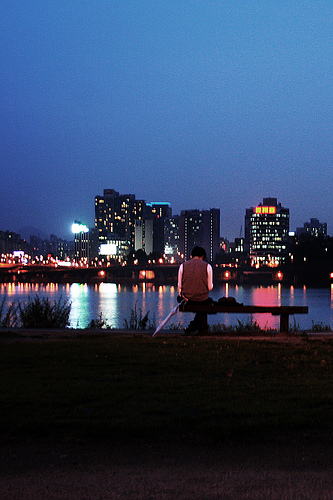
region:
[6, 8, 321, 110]
Large blue night sky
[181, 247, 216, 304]
A small boy sitting by the river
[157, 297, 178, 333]
Silver toy sword sitting by a small boy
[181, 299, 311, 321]
A black bench by the river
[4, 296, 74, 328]
Small green shrubs growing by the river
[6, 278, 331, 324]
River in front of the city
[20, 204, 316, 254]
Cityscape with large lit buildings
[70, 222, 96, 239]
Glowing blue size on building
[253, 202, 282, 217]
Glowing red sign on city building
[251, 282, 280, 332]
Red light reflection on river's surface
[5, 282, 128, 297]
The reflection of bright pretty lights on the water.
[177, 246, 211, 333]
A man deep in thought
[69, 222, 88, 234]
Bright lights that make it so people can see.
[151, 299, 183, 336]
A light colored umbrella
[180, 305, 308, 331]
A park bench for people to sit on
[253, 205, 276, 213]
Windows all light up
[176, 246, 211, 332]
Gentleman in a sweater vest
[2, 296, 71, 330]
Green foliage in the moonlight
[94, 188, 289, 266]
Pretty buildings and lights at dusk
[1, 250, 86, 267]
The signs of a night life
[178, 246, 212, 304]
the back of a man sitting on a bench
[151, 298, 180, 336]
a white umbrella leaning against a bench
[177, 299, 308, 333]
a concrete bench by the river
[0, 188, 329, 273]
the city skyline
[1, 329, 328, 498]
mown grass in a riverside park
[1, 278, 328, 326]
reflective calm water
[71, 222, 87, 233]
bright white lights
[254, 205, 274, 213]
a series of three glowing orange lights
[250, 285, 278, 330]
pink light reflecting on the water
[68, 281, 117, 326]
two lines of white light reflecting on the water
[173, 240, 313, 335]
a man sits on the end of a bench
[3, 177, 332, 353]
bench overlooks some water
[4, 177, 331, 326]
tall buildings across a body of water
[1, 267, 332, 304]
building lights reflected in some water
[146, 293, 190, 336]
an umbrella leans against a bench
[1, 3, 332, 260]
the sky is dark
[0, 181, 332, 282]
many lights illuminate a city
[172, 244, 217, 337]
man has his head bent forward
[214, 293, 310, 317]
an item of clothing is on a bench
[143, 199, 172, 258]
a tall building with a blue light on the top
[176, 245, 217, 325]
a man sitting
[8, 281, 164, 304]
the reflection of differents lights on the lake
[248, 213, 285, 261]
many building lights are on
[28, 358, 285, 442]
a lot of grass in the field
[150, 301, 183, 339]
loos like a white umbrella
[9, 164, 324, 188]
the blue sky in the background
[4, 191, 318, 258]
many buildings in the distance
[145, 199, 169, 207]
a blue light on the top of the building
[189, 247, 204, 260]
the head of the man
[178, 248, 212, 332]
a lonely man